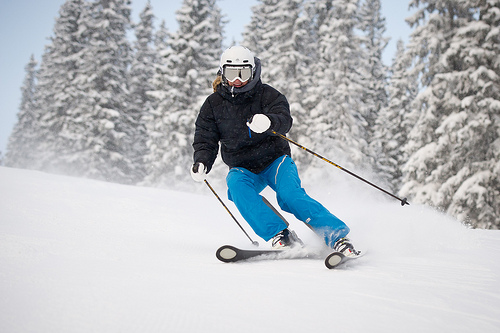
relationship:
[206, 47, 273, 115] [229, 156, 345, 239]
woman wearing pants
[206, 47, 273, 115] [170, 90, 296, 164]
woman wearing jacket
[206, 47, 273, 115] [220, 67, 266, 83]
woman wearing goggles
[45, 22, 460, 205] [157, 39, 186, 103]
trees with snow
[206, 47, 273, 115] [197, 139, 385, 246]
woman holding poles